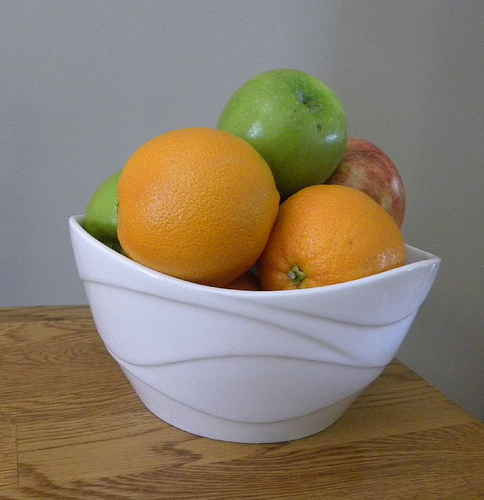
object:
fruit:
[84, 180, 131, 256]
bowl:
[69, 196, 442, 445]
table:
[2, 285, 480, 498]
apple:
[213, 71, 349, 197]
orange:
[121, 123, 278, 285]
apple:
[328, 135, 406, 237]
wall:
[9, 13, 168, 146]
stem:
[287, 262, 307, 288]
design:
[89, 279, 388, 437]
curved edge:
[70, 214, 441, 360]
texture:
[169, 175, 242, 243]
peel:
[146, 163, 221, 237]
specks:
[277, 102, 289, 114]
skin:
[247, 100, 299, 140]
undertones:
[363, 171, 375, 178]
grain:
[7, 316, 91, 497]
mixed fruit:
[88, 66, 408, 290]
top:
[182, 66, 384, 177]